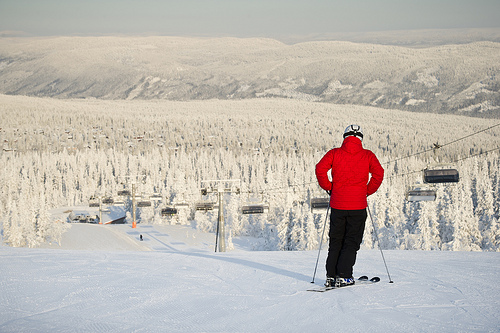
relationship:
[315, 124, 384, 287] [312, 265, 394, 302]
man on skis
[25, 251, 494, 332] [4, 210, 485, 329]
snow on ground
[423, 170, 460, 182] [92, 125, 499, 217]
seat on ski lift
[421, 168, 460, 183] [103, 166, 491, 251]
bench on ski lift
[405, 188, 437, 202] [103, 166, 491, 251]
bench on ski lift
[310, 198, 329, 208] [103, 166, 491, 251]
bench on ski lift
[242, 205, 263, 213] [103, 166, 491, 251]
bench on ski lift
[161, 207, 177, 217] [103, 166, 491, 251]
bench on ski lift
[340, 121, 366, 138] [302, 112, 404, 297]
helmet on skier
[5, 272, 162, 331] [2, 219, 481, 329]
tracks on snow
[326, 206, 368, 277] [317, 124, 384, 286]
pants on skier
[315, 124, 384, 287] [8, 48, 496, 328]
man skiing snow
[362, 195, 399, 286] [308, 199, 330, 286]
ski pole in ski pole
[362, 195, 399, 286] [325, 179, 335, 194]
ski pole in hand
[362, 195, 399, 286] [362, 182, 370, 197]
ski pole in hand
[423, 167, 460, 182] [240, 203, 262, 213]
bench on bench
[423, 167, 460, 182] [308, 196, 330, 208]
bench on bench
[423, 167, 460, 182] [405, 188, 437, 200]
bench on bench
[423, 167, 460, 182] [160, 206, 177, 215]
bench on bench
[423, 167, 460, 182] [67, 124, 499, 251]
bench on ski lift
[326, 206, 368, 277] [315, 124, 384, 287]
pants on man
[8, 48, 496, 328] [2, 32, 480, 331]
snow covers area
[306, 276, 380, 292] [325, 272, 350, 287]
skis on feet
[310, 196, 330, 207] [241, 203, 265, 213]
ski-lift car coming up ski-lift car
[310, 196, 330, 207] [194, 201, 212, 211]
ski-lift car coming up ski-lift car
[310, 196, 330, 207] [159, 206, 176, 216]
ski-lift car coming up ski-lift car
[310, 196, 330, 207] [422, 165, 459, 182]
ski-lift car coming up ski-lift car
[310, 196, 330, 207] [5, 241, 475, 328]
ski-lift car coming up mountain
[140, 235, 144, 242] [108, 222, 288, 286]
background person skiing slope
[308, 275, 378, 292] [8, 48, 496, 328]
skis in snow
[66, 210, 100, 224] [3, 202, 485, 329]
lodge at bottom of hill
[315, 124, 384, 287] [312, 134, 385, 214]
man with red coat